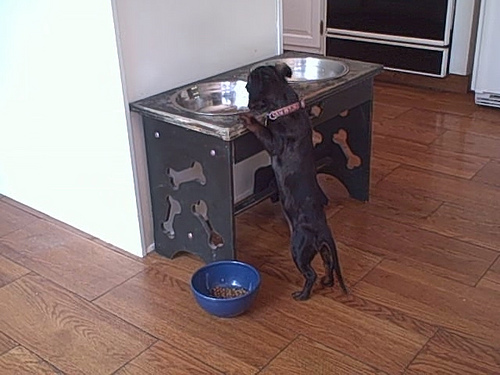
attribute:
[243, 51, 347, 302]
dog — here, little, black, standing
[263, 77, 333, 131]
collar — pink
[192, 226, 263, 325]
bowl — blue, here, big, reflecting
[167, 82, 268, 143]
bowl — silver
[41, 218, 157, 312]
floor — here, wooden, brown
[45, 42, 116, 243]
wall — here, white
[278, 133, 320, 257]
fur — black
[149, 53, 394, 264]
feeder — tall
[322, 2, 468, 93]
appliance — black, white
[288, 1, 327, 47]
sink — here, silvery, shiny